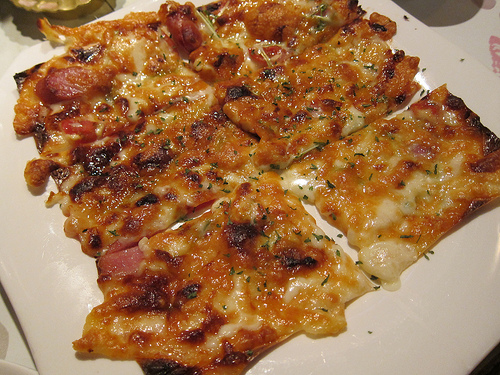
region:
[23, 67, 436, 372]
the pizza is sliced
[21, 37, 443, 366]
the cheese is toasted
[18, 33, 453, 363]
the plate is white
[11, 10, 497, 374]
the plate is rectangle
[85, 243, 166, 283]
the ham is red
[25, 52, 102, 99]
the sausage on top of the pizza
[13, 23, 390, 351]
the crust is thin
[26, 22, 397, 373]
the slices are rectangle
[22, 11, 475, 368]
six slices of pizza on the plate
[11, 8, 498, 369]
parsley on top of the pizza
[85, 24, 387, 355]
greasy food on a plate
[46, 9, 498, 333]
eight pieces of food on a plate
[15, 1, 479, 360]
white plate with food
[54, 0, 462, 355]
bits of tiny parsley and garlic on top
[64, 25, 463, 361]
a deep greasy dish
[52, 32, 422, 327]
lots of oil on the food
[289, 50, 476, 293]
neatly cut food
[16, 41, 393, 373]
cheese on top of the food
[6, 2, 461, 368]
food from a restaurant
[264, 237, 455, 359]
a speck of something on the plate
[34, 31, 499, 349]
a very tasty pizza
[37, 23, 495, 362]
a pizza cut into 6 pieces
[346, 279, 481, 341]
a white surface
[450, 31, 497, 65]
a red piece in the corner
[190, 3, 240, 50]
a green piece in the pizza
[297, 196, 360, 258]
space between two pieces of pizza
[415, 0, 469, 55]
shadow casted in the photo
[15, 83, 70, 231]
cheese hanging off the pizza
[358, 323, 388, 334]
a small dot on the white plate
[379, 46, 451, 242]
tasty corner of the pie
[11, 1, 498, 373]
Cooked pizza on dish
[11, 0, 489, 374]
Pizza cutted in slices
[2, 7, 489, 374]
Pizza is on white dish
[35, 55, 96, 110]
Slice of ham on pizza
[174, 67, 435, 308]
Green herbs on pizza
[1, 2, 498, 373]
Dish is white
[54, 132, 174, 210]
Cheese is burned in slice of pizza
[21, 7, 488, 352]
Pizza has topping cheese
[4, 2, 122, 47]
Shadow cast on table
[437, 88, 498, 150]
Border of pizza is black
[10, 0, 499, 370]
Pizza cut in slices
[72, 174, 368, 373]
Pizza slice is square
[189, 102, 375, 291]
Green herbs on top of pizza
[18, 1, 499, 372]
Cheese pizza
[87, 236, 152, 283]
Ham on slice of pizza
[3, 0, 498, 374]
Pizza on a white dish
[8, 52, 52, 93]
Corner of pizza is black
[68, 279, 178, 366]
Piece of cheese stick out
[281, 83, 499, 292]
Slice of pizza topping with cheese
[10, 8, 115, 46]
Shadow of a container